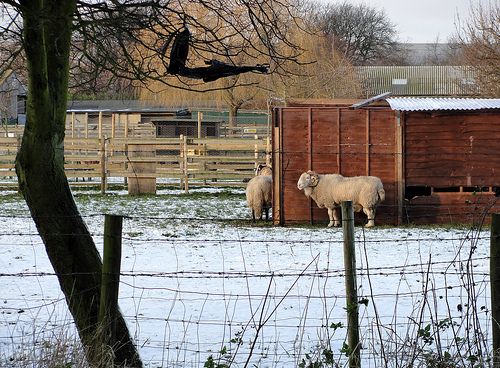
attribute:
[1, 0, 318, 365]
tree — bare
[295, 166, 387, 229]
sheep — white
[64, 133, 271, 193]
wooden fence — tan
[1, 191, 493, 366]
snow — thin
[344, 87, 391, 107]
plank — wood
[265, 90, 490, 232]
building — red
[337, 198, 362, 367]
post — tall, thin, metal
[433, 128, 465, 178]
wall — wooden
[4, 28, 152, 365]
tree trunk — thick, bending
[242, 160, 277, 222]
lamb — fluffy, white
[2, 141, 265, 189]
fence — wooden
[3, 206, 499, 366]
fence — wire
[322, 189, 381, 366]
post — gray, metal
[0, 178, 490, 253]
grass — patchy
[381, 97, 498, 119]
roof — silver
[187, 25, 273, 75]
tree — leafless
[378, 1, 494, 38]
sky — gray, empty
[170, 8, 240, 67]
branch — thin, leafless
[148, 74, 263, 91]
branch — thin, leafless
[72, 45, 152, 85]
branch — thin, leafless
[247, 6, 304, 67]
branch — thin, leafless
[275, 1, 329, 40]
branch — thin, leafless